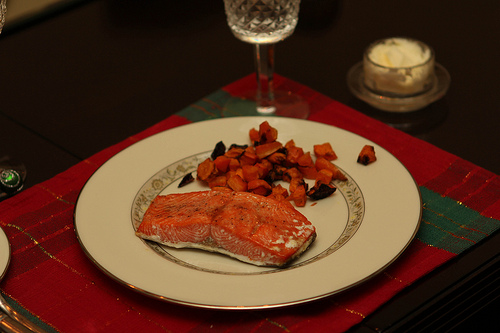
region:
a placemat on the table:
[10, 43, 489, 331]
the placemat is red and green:
[3, 49, 487, 329]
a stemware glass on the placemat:
[216, 0, 321, 125]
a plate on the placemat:
[69, 108, 429, 312]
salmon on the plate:
[137, 182, 322, 269]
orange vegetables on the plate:
[187, 112, 391, 202]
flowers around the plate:
[127, 148, 366, 269]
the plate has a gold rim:
[68, 112, 428, 318]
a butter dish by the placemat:
[337, 25, 450, 120]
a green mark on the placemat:
[0, 160, 32, 196]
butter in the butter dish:
[371, 39, 426, 71]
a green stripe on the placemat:
[196, 80, 485, 257]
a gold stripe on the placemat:
[0, 209, 169, 331]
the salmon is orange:
[140, 186, 320, 270]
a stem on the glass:
[245, 42, 282, 104]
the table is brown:
[10, 0, 492, 331]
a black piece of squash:
[310, 179, 345, 199]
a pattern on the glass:
[220, 0, 300, 42]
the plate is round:
[57, 107, 416, 307]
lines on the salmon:
[148, 183, 290, 258]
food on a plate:
[112, 104, 369, 319]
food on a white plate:
[111, 111, 493, 323]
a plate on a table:
[86, 61, 396, 319]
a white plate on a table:
[52, 68, 437, 318]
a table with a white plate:
[85, 38, 445, 318]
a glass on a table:
[162, 14, 379, 162]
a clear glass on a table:
[204, 4, 446, 153]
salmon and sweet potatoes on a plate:
[75, 114, 426, 312]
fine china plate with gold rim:
[72, 113, 422, 315]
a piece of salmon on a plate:
[137, 192, 317, 263]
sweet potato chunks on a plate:
[185, 120, 377, 203]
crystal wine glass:
[225, 2, 309, 119]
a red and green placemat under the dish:
[4, 68, 499, 332]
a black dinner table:
[7, 0, 489, 327]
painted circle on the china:
[130, 146, 365, 268]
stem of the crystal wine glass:
[254, 45, 276, 115]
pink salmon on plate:
[157, 177, 335, 279]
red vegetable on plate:
[191, 130, 379, 204]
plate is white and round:
[71, 113, 421, 305]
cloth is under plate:
[37, 71, 358, 331]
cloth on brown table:
[71, 91, 419, 329]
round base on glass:
[234, 63, 306, 127]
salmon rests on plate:
[140, 183, 317, 268]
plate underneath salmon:
[68, 112, 425, 315]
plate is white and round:
[73, 114, 424, 314]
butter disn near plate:
[339, 32, 450, 114]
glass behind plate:
[221, 0, 312, 117]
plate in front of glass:
[72, 110, 424, 318]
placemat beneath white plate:
[1, 64, 499, 331]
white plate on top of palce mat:
[69, 112, 424, 315]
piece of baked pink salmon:
[139, 187, 316, 269]